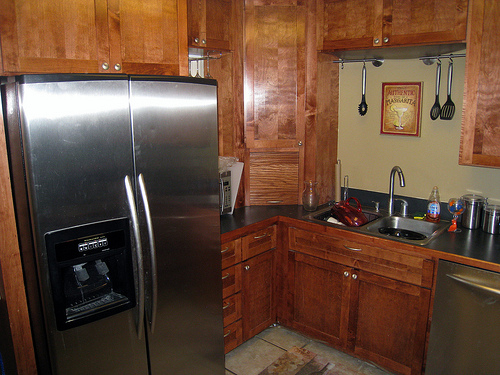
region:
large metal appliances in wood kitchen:
[5, 8, 495, 365]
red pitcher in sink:
[302, 185, 372, 236]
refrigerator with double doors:
[0, 65, 225, 370]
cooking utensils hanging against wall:
[351, 50, 456, 116]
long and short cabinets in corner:
[205, 0, 331, 207]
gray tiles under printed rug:
[227, 321, 377, 371]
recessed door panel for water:
[37, 211, 137, 326]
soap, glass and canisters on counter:
[421, 176, 496, 236]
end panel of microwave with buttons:
[217, 161, 232, 213]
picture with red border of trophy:
[377, 78, 422, 138]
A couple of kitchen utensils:
[429, 58, 456, 120]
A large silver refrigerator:
[7, 81, 224, 373]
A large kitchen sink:
[307, 165, 445, 243]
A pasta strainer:
[357, 65, 369, 115]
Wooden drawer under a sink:
[289, 224, 430, 283]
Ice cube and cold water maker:
[46, 217, 135, 325]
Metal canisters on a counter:
[462, 194, 499, 233]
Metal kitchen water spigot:
[385, 162, 405, 215]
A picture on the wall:
[379, 82, 422, 136]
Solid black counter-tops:
[221, 183, 497, 264]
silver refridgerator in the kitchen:
[0, 73, 225, 373]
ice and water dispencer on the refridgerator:
[42, 215, 139, 328]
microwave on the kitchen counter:
[217, 165, 236, 215]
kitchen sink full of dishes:
[308, 204, 443, 248]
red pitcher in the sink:
[328, 195, 365, 228]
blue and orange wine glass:
[445, 195, 466, 235]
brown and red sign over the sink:
[377, 81, 424, 136]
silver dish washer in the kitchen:
[422, 257, 498, 374]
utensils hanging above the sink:
[332, 50, 464, 122]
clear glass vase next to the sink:
[300, 179, 318, 212]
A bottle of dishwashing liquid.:
[426, 182, 442, 221]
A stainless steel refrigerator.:
[3, 71, 226, 370]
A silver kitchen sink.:
[317, 161, 451, 256]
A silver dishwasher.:
[419, 259, 497, 372]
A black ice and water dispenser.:
[42, 217, 135, 332]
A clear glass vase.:
[300, 179, 318, 211]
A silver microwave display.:
[221, 172, 231, 214]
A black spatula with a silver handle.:
[439, 61, 456, 119]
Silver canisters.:
[461, 192, 498, 234]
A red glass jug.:
[332, 197, 368, 227]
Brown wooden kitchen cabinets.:
[2, 2, 492, 373]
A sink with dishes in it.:
[312, 191, 440, 248]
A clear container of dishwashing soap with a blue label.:
[425, 188, 442, 221]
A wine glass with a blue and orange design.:
[442, 201, 467, 233]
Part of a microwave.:
[218, 172, 233, 216]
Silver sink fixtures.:
[368, 161, 418, 220]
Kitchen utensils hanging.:
[354, 51, 466, 124]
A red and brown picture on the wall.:
[381, 80, 423, 136]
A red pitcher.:
[330, 196, 370, 228]